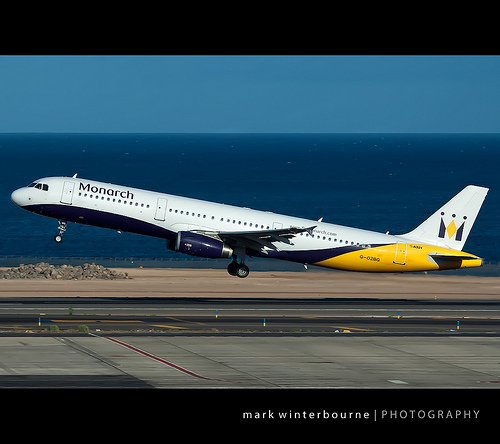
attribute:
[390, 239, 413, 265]
door — yellow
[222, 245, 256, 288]
wheels — black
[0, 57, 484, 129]
sky — clear, blue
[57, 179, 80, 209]
door — small, white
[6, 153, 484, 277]
plane turbine — navy, silver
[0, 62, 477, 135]
sky — cloudless, bright, blue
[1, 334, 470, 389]
runway — light grey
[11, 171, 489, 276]
plane — off, flying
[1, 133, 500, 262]
ocean — blue, calm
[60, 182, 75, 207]
door — white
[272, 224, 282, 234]
door — white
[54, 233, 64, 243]
tire — black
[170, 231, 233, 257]
engine — blue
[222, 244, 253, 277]
landing gear — down, black, grey